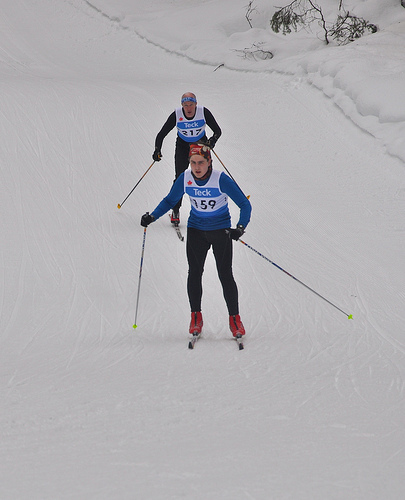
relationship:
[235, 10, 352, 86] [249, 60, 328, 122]
tree in snow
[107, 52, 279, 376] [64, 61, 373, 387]
competitors skiing on slope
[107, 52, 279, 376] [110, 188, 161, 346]
competitor holding pole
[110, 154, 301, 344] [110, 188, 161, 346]
competitor holding pole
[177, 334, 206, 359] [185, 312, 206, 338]
tip of shoes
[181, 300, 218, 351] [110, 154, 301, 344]
part of skater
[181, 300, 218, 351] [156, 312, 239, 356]
part of shoes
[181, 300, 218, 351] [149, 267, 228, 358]
part of hooker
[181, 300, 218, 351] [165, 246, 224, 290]
part of trouser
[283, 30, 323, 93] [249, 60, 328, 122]
part of snow